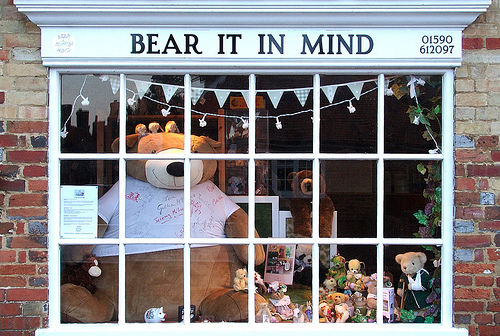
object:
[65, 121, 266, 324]
bear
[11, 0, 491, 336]
window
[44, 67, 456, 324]
frame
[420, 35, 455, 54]
numbers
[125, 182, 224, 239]
writing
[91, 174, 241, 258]
shirt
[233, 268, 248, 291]
bear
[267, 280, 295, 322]
bear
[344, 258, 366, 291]
bear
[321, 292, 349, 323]
bear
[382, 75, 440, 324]
vine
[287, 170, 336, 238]
bear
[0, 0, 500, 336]
bricks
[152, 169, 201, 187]
smile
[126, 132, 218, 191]
face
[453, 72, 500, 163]
wall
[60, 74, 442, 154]
lights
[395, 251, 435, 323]
bear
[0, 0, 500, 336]
building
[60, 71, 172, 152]
reflection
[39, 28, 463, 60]
sign